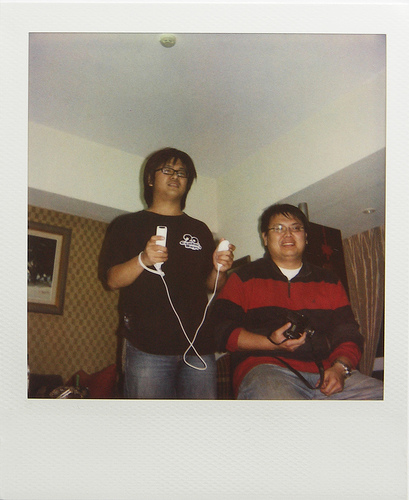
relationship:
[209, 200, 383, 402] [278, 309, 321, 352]
boy holding camera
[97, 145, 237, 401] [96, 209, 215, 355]
boy wearing shirt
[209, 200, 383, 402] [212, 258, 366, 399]
boy wearing rugby shirt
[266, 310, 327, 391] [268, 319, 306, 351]
camera in hand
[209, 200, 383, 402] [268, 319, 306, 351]
boy has hand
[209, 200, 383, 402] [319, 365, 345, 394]
boy has hand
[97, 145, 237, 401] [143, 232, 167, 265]
boy has hand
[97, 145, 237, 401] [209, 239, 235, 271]
boy has hand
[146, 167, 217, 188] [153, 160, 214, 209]
eyeglasses on face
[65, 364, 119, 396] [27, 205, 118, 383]
pillow against wall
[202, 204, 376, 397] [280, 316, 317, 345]
boy holding camera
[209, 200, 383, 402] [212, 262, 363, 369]
boy wearing rugby shirt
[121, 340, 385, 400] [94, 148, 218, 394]
jeans worn by boy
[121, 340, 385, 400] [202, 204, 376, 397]
jeans worn by boy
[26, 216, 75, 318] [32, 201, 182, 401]
picture hanging on wall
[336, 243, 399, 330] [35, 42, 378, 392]
curtains in living room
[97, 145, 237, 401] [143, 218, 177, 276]
boy holding remote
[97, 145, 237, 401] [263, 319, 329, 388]
boy holding camera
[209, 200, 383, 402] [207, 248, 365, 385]
boy wearing shirt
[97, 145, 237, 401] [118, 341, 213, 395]
boy wearing jeans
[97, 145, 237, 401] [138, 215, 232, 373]
boy holding controller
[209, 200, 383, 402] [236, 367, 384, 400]
boy wearing jeans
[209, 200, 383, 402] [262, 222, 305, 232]
boy wearing glasses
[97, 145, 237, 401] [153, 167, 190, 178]
boy wearing eyeglasses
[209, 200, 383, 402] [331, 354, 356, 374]
boy wearing watch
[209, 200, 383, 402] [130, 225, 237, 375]
boy holding game controllers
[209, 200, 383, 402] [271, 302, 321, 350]
boy holding camera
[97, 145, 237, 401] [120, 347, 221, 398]
boy wearing jeans